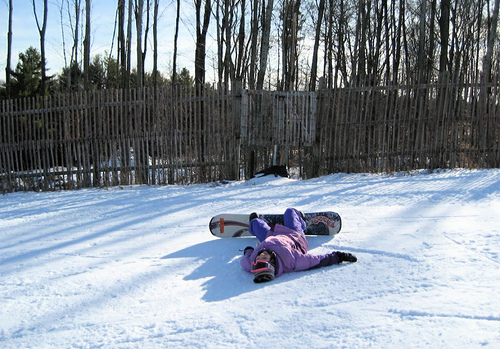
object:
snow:
[0, 171, 500, 349]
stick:
[0, 76, 500, 193]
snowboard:
[207, 211, 341, 239]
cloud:
[0, 0, 496, 87]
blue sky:
[1, 1, 499, 95]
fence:
[3, 72, 500, 194]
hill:
[2, 169, 498, 347]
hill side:
[0, 167, 495, 346]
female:
[240, 208, 358, 284]